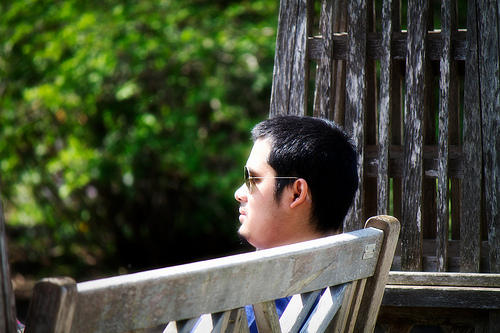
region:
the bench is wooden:
[22, 145, 466, 328]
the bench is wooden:
[138, 138, 338, 330]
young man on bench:
[53, 71, 410, 320]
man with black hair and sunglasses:
[198, 103, 380, 288]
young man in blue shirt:
[165, 100, 390, 329]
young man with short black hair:
[138, 69, 383, 325]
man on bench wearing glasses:
[156, 87, 393, 332]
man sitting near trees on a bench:
[101, 73, 453, 332]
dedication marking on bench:
[352, 238, 383, 263]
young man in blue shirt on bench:
[88, 78, 358, 332]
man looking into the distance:
[121, 92, 362, 326]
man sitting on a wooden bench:
[161, 72, 379, 323]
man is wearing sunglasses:
[230, 151, 326, 193]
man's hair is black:
[247, 79, 379, 264]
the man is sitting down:
[104, 47, 398, 322]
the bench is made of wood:
[4, 174, 424, 331]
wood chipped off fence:
[272, 2, 470, 267]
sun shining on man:
[215, 110, 390, 282]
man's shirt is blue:
[208, 253, 328, 331]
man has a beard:
[233, 225, 257, 248]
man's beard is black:
[235, 220, 271, 252]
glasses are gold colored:
[223, 159, 306, 184]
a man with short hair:
[80, 27, 447, 319]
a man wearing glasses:
[126, 40, 404, 317]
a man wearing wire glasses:
[98, 52, 482, 330]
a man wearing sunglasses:
[184, 12, 464, 324]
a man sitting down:
[96, 60, 376, 323]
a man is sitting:
[89, 77, 469, 330]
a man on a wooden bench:
[35, 60, 485, 295]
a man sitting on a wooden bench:
[44, 85, 399, 326]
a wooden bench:
[22, 132, 318, 317]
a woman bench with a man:
[143, 102, 494, 312]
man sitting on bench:
[28, 99, 409, 331]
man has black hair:
[221, 112, 365, 248]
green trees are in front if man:
[6, 0, 190, 241]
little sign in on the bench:
[347, 237, 392, 274]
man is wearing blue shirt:
[238, 113, 331, 323]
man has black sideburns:
[266, 163, 293, 210]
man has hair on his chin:
[231, 226, 256, 238]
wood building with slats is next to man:
[227, 11, 499, 276]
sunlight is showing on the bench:
[231, 295, 354, 331]